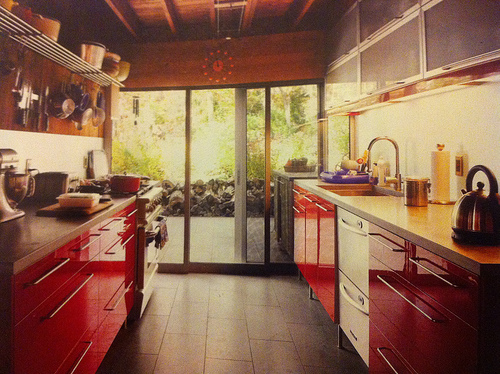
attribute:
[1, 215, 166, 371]
drawers — red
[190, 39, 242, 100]
clock — orange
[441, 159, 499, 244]
kettle — silver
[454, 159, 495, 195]
handle — black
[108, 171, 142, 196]
pot — red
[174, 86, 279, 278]
sliding door — glass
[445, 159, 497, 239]
tea kettle — chrome, black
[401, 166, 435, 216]
canister — chrome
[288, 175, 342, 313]
cabinet doors — red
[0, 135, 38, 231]
mixer — large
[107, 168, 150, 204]
pot — red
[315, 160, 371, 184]
holder — purple, dish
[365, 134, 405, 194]
faucet — stainless steel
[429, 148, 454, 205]
towels — white, paper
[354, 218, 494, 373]
cabinets — red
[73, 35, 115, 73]
pot — stainless, cooking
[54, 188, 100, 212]
container — white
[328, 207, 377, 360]
dishwasher — white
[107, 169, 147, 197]
pot — red, stock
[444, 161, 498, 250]
kettle — stainless steel, water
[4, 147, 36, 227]
mixer — silver, kitchen aid, stand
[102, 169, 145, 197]
pot — red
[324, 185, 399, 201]
sink — single, large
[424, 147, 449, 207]
towels — roll, paper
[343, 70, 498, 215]
wall — kitchen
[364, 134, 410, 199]
faucet — chrome, sink, curved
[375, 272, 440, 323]
handle — long, chrome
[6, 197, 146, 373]
cabinets — shiny, red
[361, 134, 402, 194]
faucet — sink, high arch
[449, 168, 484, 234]
tea kettle — black